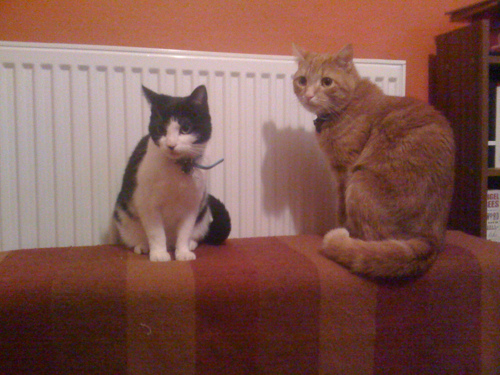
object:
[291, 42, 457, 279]
brown cat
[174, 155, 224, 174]
collar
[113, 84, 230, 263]
cat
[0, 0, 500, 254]
ground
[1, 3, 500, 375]
wall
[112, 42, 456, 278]
cat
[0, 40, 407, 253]
back rest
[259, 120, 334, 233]
shadow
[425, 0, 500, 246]
book shelf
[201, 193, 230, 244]
tail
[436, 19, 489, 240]
cabinet door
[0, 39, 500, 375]
chair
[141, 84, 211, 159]
head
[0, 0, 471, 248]
bench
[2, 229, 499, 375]
ottoman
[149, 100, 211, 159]
face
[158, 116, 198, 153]
markings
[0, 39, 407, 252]
back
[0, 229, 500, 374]
bench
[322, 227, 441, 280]
tail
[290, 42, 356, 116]
head